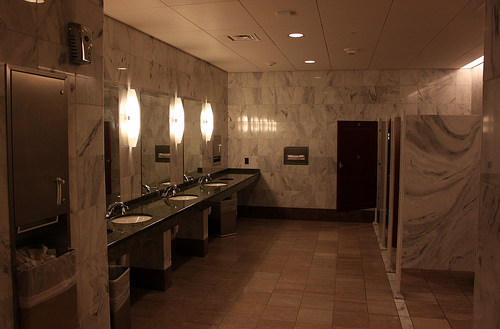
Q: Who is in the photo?
A: No one.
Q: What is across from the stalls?
A: Sinks.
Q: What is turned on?
A: Lights.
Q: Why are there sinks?
A: So people can wash their hands.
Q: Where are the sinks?
A: On the left.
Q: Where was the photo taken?
A: In a bathroom.